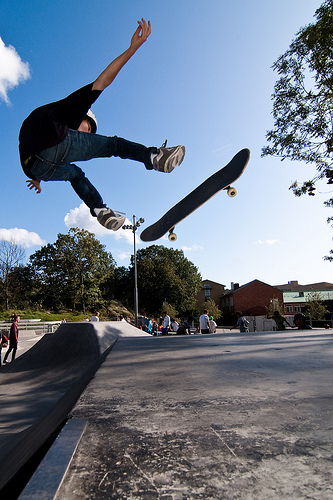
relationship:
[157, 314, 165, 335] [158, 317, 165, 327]
person with shirt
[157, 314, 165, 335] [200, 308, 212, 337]
person with shirts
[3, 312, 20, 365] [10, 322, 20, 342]
person with shirt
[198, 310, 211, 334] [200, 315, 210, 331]
person wearing shirt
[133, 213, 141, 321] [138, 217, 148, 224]
pole with light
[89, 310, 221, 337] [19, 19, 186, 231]
people watching skater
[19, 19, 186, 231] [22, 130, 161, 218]
skater wearing jeans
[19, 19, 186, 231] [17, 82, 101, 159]
skater wearing shirt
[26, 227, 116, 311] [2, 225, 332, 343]
tree in background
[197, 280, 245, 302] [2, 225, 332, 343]
house in background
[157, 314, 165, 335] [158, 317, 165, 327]
person wearing shirt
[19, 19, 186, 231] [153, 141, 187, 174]
skater wearing shoe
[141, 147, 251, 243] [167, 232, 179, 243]
skateboard with wheel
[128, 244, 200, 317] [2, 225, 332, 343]
tree in background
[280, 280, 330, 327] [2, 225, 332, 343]
building in background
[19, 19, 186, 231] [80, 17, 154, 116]
skater with arm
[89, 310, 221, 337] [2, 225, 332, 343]
people in background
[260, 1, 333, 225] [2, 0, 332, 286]
tree against sky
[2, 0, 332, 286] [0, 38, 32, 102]
sky with cloud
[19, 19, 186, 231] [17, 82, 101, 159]
skater in shirt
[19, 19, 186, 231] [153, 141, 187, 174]
skater in shoe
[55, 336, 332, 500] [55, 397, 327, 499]
concrete has stain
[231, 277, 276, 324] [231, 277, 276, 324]
building has building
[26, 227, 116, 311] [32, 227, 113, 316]
tree with leaves